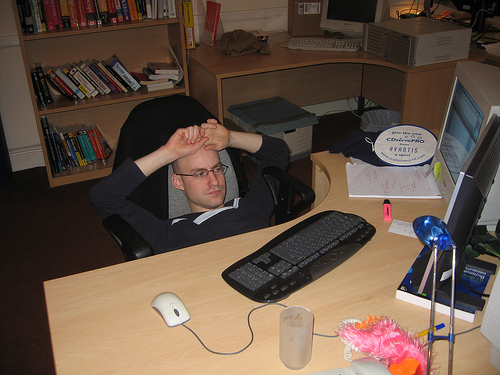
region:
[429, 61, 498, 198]
A small television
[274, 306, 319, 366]
A drinking glass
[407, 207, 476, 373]
A desk lamp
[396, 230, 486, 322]
A textbook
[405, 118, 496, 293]
A grey and black computer monitor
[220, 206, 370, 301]
A wireless computer keyboard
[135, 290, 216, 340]
A white computer mouse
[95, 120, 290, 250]
A black computer chair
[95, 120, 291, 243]
A man in a blue and white shirt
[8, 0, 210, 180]
A large wooden book shelf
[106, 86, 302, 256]
a man sitting on a chair.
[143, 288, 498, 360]
a mouse with a wire.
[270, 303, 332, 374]
a glass on a desk.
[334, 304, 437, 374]
a pink object on a desk.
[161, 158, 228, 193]
a man wearing glasses.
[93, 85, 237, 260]
a black seat at a desk.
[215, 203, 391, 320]
a black keyboard on a desk.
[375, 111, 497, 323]
a computer screen.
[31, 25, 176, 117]
a set of books on a book shelf.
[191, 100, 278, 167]
a left human arm.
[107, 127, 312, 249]
man slumping in chair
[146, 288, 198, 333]
white mouse on desk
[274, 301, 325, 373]
cup on desk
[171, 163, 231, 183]
glasses of man on chair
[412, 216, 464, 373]
blue lamp on the desk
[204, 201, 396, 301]
black wireless keyboard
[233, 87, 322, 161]
file box on the floor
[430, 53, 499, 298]
computer monitors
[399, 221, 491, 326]
book that monitor is propped on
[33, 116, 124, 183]
books on lowest bookshelf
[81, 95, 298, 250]
Man slouched down in chair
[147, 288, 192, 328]
White mouse on table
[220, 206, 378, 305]
Black computer keyboard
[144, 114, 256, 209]
Man with his hands on his head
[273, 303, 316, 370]
Empty glass on the table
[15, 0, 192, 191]
Books in a bookshelf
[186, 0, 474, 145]
Desek with no one at it against wall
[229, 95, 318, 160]
Storage bin on floor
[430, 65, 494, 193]
Computer monitor turned on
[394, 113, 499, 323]
Computer monitor on top of a book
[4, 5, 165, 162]
Books in a bookcase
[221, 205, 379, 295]
A black computer keyboard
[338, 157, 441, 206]
A white tablet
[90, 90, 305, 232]
A man slouched in a chair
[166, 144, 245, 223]
A man wearing glasses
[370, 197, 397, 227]
A pink highlighter with a black cap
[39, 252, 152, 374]
The corner of a light colored desk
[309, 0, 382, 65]
A desktop computer and keyboard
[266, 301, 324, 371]
An empty cup